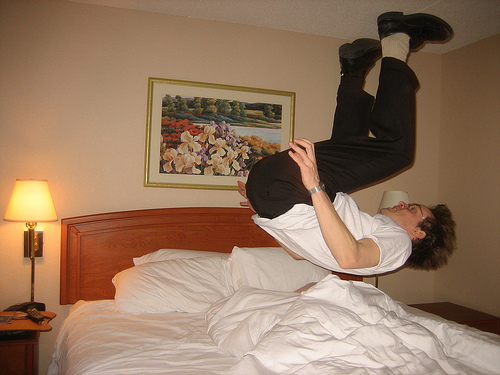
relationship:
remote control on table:
[25, 305, 44, 322] [1, 311, 56, 373]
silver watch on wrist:
[302, 179, 327, 198] [307, 170, 345, 214]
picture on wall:
[147, 71, 302, 195] [18, 54, 434, 286]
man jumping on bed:
[241, 8, 462, 275] [51, 289, 499, 374]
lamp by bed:
[7, 145, 84, 333] [38, 194, 433, 358]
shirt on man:
[225, 199, 417, 284] [185, 8, 485, 306]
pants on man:
[240, 57, 422, 214] [241, 8, 462, 275]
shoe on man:
[374, 7, 456, 54] [241, 8, 462, 275]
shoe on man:
[335, 36, 382, 78] [241, 8, 462, 275]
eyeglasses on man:
[392, 195, 434, 225] [294, 155, 486, 261]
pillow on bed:
[108, 258, 235, 318] [68, 182, 441, 370]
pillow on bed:
[108, 258, 229, 318] [100, 207, 441, 369]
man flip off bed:
[241, 8, 462, 275] [46, 250, 498, 374]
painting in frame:
[158, 90, 284, 183] [123, 62, 305, 204]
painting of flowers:
[158, 93, 284, 182] [177, 138, 272, 162]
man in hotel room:
[241, 8, 462, 275] [16, 18, 451, 373]